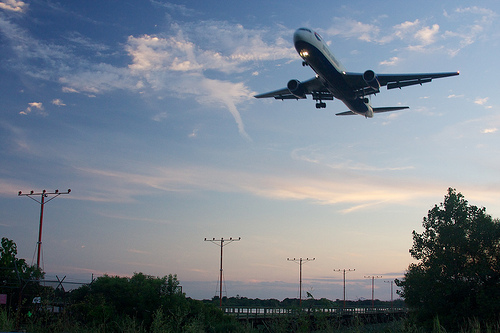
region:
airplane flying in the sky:
[257, 22, 459, 124]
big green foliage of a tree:
[394, 188, 498, 325]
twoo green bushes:
[6, 236, 193, 326]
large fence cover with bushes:
[79, 296, 413, 331]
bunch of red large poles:
[14, 187, 410, 321]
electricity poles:
[16, 188, 398, 310]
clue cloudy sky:
[7, 1, 497, 296]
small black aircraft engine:
[308, 83, 329, 105]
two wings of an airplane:
[237, 64, 460, 103]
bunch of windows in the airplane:
[321, 35, 349, 77]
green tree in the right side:
[399, 194, 499, 324]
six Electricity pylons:
[18, 182, 418, 318]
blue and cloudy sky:
[3, 3, 498, 303]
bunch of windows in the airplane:
[319, 42, 346, 75]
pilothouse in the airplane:
[290, 27, 315, 38]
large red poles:
[13, 188, 400, 310]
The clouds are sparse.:
[118, 40, 229, 107]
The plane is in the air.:
[241, 19, 446, 165]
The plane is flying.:
[252, 28, 410, 151]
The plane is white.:
[264, 26, 461, 151]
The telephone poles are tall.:
[14, 184, 387, 314]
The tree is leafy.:
[415, 208, 486, 318]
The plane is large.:
[252, 21, 416, 140]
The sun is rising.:
[75, 51, 485, 316]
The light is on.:
[290, 47, 315, 67]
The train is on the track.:
[95, 280, 336, 331]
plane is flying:
[241, 16, 466, 130]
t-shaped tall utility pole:
[7, 179, 80, 286]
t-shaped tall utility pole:
[203, 233, 245, 300]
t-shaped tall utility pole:
[277, 254, 319, 303]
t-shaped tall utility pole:
[327, 261, 359, 304]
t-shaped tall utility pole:
[361, 271, 386, 301]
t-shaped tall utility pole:
[380, 277, 404, 298]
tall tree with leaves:
[402, 187, 494, 322]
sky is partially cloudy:
[4, 2, 249, 170]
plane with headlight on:
[249, 20, 463, 138]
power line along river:
[20, 175, 60, 283]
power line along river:
[203, 230, 238, 300]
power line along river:
[284, 251, 311, 306]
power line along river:
[331, 255, 358, 300]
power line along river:
[359, 271, 385, 294]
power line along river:
[381, 280, 399, 301]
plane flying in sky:
[251, 12, 442, 132]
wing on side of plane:
[356, 62, 456, 88]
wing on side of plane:
[263, 77, 327, 109]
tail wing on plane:
[340, 100, 406, 127]